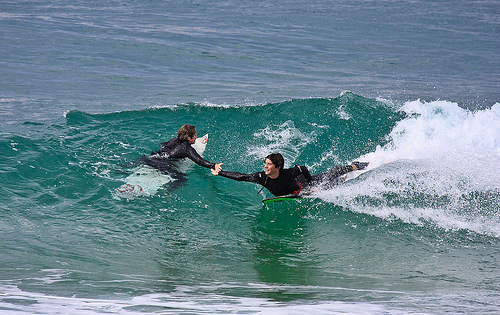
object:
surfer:
[209, 154, 370, 198]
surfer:
[114, 123, 223, 198]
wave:
[57, 92, 500, 235]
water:
[1, 2, 497, 315]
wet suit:
[128, 138, 214, 190]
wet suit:
[218, 164, 355, 197]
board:
[116, 134, 208, 201]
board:
[262, 196, 305, 206]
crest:
[56, 91, 396, 120]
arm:
[216, 170, 264, 184]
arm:
[183, 146, 217, 170]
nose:
[195, 131, 209, 154]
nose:
[262, 197, 276, 205]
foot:
[351, 161, 371, 171]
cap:
[264, 152, 286, 172]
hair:
[177, 124, 197, 141]